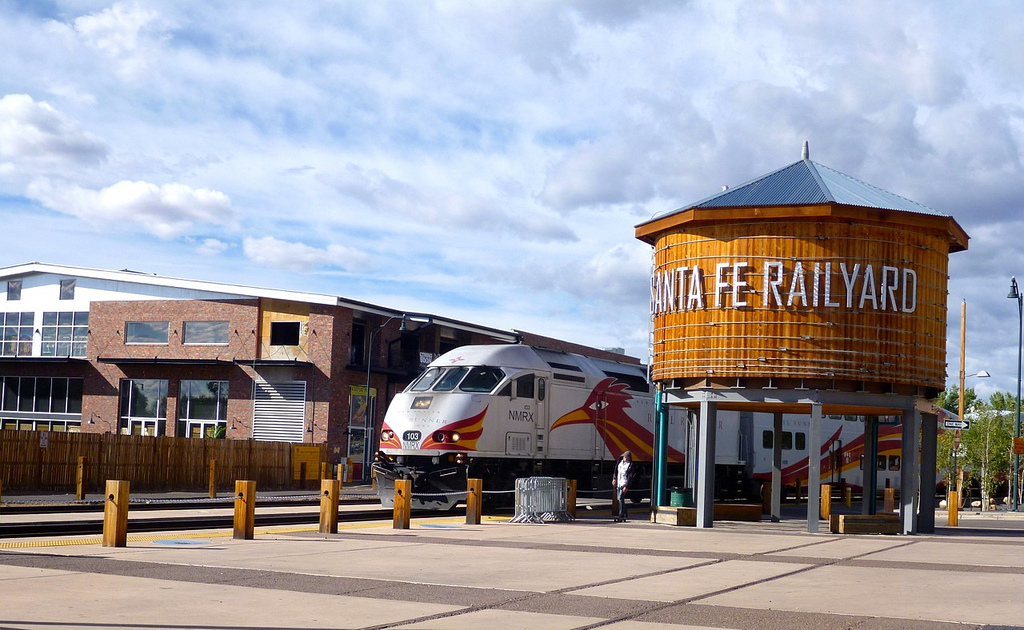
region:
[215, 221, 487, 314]
A blue sky with clouds.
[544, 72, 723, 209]
A fluffy and gray cloud.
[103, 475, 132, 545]
A small yellow post near the track.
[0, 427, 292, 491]
A wooden fence near the railings.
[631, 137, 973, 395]
A wooden tank with white letterings.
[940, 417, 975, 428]
A small signage with white arrow.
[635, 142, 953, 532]
a big water tower sitting on a platform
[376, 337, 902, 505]
a colorful train sitting on the track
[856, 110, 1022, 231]
a grey cloud sitting back in the corner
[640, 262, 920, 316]
the name of the place on the water tower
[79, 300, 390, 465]
a brick building with many windows on it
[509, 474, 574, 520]
a small metal box next to the train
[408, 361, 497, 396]
the front windows of the train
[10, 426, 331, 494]
a wooden fence next to the platform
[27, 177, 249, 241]
white cloud in sky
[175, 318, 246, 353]
window on the building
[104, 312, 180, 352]
window on the building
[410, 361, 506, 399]
windows on front of train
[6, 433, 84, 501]
fence surrounding the building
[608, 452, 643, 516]
man next to train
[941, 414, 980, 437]
one way sign on pole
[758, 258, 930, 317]
white letters on tower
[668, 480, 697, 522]
green garbage can outside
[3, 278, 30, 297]
a window on a building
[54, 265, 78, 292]
a window on a building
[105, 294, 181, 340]
a window on a building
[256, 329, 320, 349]
a window on a building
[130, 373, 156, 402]
a window on a building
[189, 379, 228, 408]
a window on a building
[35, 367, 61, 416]
a window on a building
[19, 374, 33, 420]
a window on a building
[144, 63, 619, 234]
white clouds in a blue sky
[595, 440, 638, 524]
a person standing next to a train car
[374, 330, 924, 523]
a train car on train tracks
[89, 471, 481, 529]
short metal post painted yellow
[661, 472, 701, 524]
a green garbage can lined with a black bag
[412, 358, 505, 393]
the windshield on a train car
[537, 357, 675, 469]
a red and yellow chicken painted on a train car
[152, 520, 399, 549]
a yellow line painted on a plat form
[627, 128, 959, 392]
a round structure with a tin roof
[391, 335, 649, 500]
train pulling into the station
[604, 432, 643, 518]
person standing on the platform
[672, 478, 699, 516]
trash can is green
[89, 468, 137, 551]
yellow barrier on the platform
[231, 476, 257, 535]
yellow barrier on the platform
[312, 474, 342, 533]
yellow barrier on the platform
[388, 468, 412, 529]
yellow barrier on the platform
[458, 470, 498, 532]
yellow barrier on the platform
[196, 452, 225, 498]
yellow barrier on the platform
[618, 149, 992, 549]
santa fe railyard water tower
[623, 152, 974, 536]
santa fe railyard water tower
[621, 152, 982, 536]
santa fe railyard water tower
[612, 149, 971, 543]
santa fe railyard water tower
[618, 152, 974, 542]
santa fe railyard water tower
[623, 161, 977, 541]
santa fe railyard water tower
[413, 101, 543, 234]
clouds in the sky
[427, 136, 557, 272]
the clouds are white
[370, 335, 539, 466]
a train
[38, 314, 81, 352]
windows on the building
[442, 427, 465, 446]
headlight on the train